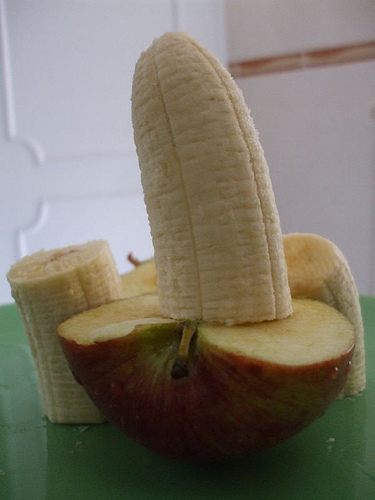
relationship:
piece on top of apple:
[132, 30, 295, 322] [58, 284, 357, 471]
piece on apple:
[132, 30, 295, 322] [58, 284, 357, 471]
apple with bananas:
[58, 284, 357, 471] [127, 35, 294, 326]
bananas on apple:
[127, 35, 294, 326] [58, 284, 357, 471]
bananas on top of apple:
[127, 35, 294, 326] [58, 284, 357, 471]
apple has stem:
[58, 284, 357, 471] [171, 326, 199, 381]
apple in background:
[119, 259, 162, 298] [4, 0, 374, 373]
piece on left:
[7, 236, 124, 440] [3, 0, 171, 498]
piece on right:
[281, 230, 371, 399] [219, 0, 373, 495]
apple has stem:
[119, 259, 162, 298] [127, 247, 144, 269]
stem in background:
[127, 247, 144, 269] [4, 0, 374, 373]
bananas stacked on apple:
[127, 35, 294, 326] [58, 284, 357, 471]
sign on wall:
[223, 36, 374, 82] [218, 0, 374, 294]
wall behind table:
[5, 3, 233, 300] [7, 293, 373, 494]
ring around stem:
[178, 323, 198, 357] [171, 326, 199, 381]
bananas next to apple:
[127, 35, 294, 326] [58, 284, 357, 471]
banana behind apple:
[8, 240, 120, 428] [58, 284, 357, 471]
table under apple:
[7, 293, 373, 494] [58, 284, 357, 471]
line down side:
[148, 42, 190, 308] [138, 46, 276, 319]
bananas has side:
[127, 35, 294, 326] [138, 46, 276, 319]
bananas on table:
[127, 35, 294, 326] [7, 293, 373, 494]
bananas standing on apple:
[127, 35, 294, 326] [58, 284, 357, 471]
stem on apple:
[171, 326, 199, 381] [58, 284, 357, 471]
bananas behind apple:
[8, 231, 371, 410] [58, 284, 357, 471]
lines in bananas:
[152, 38, 283, 315] [127, 35, 294, 326]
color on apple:
[134, 321, 202, 383] [58, 284, 357, 471]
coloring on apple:
[101, 361, 296, 443] [58, 284, 357, 471]